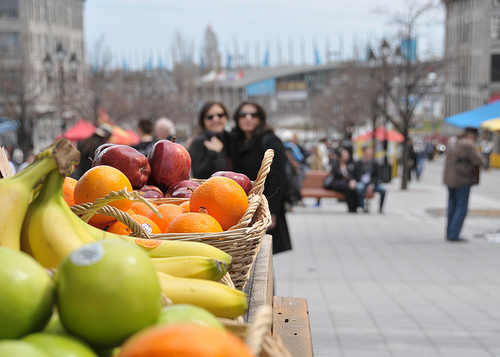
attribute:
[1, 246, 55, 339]
apple — green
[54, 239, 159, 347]
apple — green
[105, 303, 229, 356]
apple — green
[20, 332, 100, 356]
apple — green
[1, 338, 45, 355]
apple — green